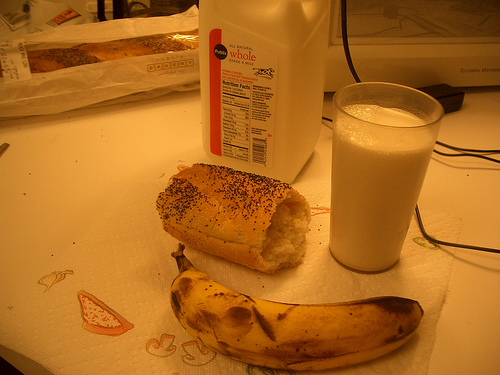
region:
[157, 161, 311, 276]
Piece of bread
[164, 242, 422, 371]
A banana that's yellow and brown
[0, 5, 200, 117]
Bread in a plastic bag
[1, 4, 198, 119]
White and clear colored plastic bag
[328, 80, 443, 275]
A clear colored glass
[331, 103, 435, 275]
Milk in a clear glass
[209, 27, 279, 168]
White, black, and red colored label on container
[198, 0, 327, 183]
White colored plastic milk container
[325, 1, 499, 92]
white colored microwave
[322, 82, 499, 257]
Black colored electronic cord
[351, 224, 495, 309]
white tissue on table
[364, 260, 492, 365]
white tissue on table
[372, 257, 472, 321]
white tissue on table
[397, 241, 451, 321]
white tissue on table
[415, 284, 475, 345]
white tissue on table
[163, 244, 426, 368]
a banana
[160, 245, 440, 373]
a yellow banana with brown bruises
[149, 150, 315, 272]
a chunk of bread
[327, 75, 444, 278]
a glass of milk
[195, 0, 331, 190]
a jug of milk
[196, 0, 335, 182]
a jug of whole milk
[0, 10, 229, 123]
a loaf of bread in a bag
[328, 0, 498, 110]
a television is on the table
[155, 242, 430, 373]
a banana is on the table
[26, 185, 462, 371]
a napkin with pictures of vegetables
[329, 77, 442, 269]
the clear cup of milk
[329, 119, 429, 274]
the white milk in the cup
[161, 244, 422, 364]
the unpeeled banana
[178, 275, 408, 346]
the brown marks on the banana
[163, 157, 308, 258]
the piece of bread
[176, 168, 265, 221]
the brown seeds on the bread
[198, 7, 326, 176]
the plastic milk jug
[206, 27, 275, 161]
the label on the milk jug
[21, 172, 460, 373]
the napkin under the milk on food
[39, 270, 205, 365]
the designs on the napkin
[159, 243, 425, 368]
banana turning brown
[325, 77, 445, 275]
glass of white milk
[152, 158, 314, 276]
piece of French bread topped with poppyseeds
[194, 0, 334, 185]
plastic half-gallon of whole milk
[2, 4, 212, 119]
loaf of bread in a bag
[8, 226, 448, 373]
paper towel under the food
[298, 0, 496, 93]
white toaster oven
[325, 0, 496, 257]
toaster oven cord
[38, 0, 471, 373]
food on the table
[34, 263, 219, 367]
pattern on the paper towel